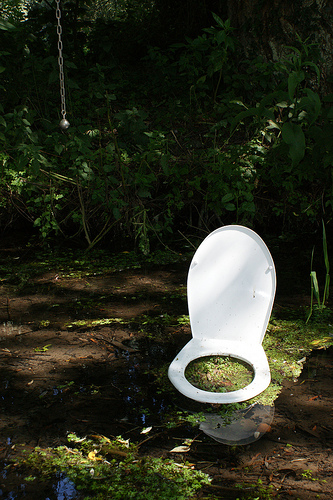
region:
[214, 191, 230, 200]
a green leaf of a tree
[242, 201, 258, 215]
a green leaf of a tree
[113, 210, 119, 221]
a green leaf of a tree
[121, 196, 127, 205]
a green leaf of a tree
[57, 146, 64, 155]
a green leaf of a tree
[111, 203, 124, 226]
a green leaf of a tree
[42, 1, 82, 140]
Metal chain hanging down.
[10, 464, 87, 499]
Puddle of water by grass.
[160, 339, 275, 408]
A white toilet seat.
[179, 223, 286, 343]
A white toilet seat cover.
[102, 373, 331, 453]
water surrounding a toilet bowl.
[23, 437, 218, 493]
Grass floating on water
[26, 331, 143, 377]
Twigs lying on some dirt.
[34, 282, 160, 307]
Patch of brown dirt.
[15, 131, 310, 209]
Row of dense bushes.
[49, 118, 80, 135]
Ball at the tip of a chain.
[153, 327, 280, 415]
this is a toilet seat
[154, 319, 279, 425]
the toilet seat is white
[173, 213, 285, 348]
lid of the seat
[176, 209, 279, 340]
the lid is white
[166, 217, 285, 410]
the lid is open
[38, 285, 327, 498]
water on the ground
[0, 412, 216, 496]
a patch of grass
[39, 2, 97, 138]
a chain hanging down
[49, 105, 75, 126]
ball at the end of the chain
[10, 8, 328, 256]
greenery in the background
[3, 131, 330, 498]
toilet seat on the ground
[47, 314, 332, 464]
water on the ground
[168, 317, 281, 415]
the seat is white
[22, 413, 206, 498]
patch of weeds on ground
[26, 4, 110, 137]
a chain hanging down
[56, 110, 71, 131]
ball on the end of chain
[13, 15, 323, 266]
green weeds in background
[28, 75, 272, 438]
this is a garden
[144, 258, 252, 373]
this is a toilet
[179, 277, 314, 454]
the toilet is white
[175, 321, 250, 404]
there are plants in the toilet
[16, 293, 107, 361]
the ground is brown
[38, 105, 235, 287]
the plants are in the background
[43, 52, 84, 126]
the chain is hanging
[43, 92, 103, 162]
the chain is metal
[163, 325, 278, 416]
this is a toilet seat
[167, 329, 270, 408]
the toilet seat is white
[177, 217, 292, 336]
lid of the seat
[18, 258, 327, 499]
A brown dirt ground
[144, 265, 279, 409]
A toilet top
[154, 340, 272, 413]
The seat of the toilet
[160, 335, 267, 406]
A toilet seat in the garden